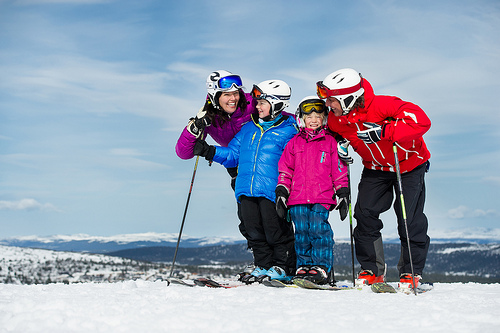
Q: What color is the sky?
A: Blue.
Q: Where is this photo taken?
A: On a ski slope.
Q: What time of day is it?
A: Daytime.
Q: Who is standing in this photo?
A: A man, woman and children.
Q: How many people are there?
A: Four.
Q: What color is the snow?
A: White.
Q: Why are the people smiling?
A: They are happy.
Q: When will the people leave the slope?
A: When they have finished skiing.